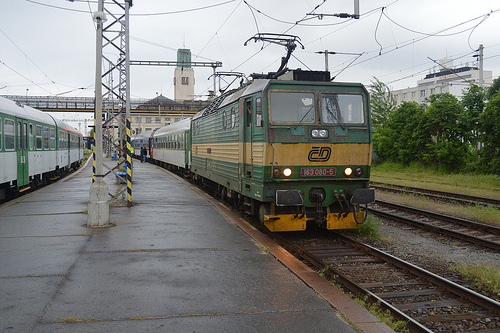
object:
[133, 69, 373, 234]
train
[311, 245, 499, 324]
railroad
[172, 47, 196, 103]
tower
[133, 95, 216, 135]
building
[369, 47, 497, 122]
building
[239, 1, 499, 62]
wires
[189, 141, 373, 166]
stripe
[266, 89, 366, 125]
windshield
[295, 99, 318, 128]
wipers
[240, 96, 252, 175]
door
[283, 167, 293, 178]
headlights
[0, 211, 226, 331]
ground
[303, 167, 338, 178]
plate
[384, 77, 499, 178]
trees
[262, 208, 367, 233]
stoppers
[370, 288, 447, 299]
tie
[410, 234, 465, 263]
gravel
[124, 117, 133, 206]
pole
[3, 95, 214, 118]
bridge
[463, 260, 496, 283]
grass